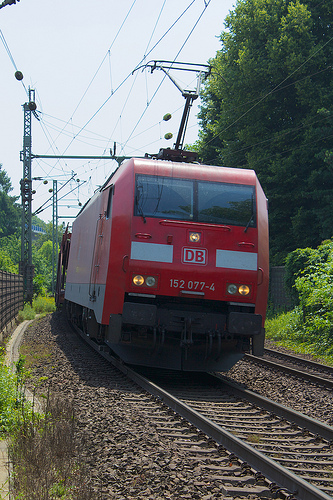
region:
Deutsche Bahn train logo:
[180, 244, 209, 265]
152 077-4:
[168, 277, 216, 292]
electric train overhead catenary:
[5, 41, 92, 188]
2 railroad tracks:
[259, 360, 328, 496]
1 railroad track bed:
[3, 356, 331, 493]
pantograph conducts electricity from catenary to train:
[135, 58, 224, 164]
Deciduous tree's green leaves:
[218, 2, 295, 59]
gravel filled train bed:
[76, 391, 180, 498]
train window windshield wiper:
[132, 180, 148, 223]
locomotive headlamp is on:
[237, 282, 251, 296]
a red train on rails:
[48, 150, 286, 386]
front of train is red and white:
[114, 156, 267, 312]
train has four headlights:
[124, 270, 260, 298]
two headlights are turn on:
[128, 270, 254, 301]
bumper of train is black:
[104, 297, 271, 378]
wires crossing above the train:
[16, 126, 221, 165]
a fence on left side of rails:
[0, 263, 29, 331]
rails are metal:
[97, 374, 332, 498]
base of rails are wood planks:
[117, 377, 332, 492]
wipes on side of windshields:
[122, 180, 263, 237]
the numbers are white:
[164, 272, 223, 299]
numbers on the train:
[160, 278, 227, 302]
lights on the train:
[132, 277, 259, 299]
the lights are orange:
[130, 277, 260, 306]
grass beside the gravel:
[12, 390, 157, 482]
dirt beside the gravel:
[9, 329, 70, 415]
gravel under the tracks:
[115, 389, 331, 470]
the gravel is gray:
[86, 390, 210, 482]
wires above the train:
[60, 49, 180, 164]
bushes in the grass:
[278, 249, 330, 355]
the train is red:
[100, 231, 215, 340]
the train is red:
[82, 207, 191, 372]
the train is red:
[109, 269, 222, 430]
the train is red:
[95, 272, 157, 332]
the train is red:
[95, 307, 149, 375]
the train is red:
[106, 254, 182, 353]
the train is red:
[151, 306, 232, 451]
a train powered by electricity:
[66, 165, 273, 382]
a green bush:
[287, 254, 331, 349]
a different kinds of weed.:
[4, 352, 85, 498]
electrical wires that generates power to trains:
[92, 35, 158, 134]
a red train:
[65, 158, 275, 369]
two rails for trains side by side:
[134, 352, 327, 481]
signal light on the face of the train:
[126, 269, 157, 287]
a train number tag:
[166, 276, 217, 293]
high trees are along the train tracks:
[207, 79, 330, 161]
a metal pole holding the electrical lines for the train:
[20, 89, 43, 303]